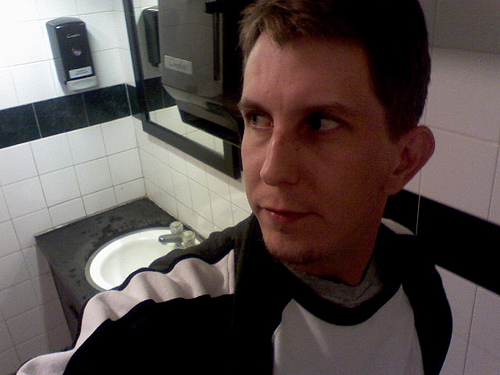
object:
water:
[100, 216, 116, 231]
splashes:
[110, 211, 121, 220]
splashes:
[102, 223, 117, 235]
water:
[94, 212, 114, 230]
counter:
[35, 192, 203, 302]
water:
[89, 220, 108, 234]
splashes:
[93, 214, 103, 221]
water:
[59, 218, 87, 234]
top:
[27, 222, 457, 375]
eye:
[298, 110, 351, 133]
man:
[15, 8, 455, 375]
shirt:
[20, 194, 454, 375]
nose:
[259, 119, 300, 187]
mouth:
[257, 202, 319, 226]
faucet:
[157, 223, 195, 247]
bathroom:
[0, 0, 499, 373]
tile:
[74, 157, 114, 196]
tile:
[421, 43, 497, 143]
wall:
[128, 7, 498, 372]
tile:
[100, 116, 136, 155]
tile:
[65, 125, 109, 164]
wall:
[2, 2, 145, 373]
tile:
[41, 172, 79, 206]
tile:
[0, 217, 19, 258]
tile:
[106, 152, 144, 186]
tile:
[49, 197, 84, 231]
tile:
[0, 175, 49, 218]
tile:
[2, 146, 36, 174]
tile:
[115, 177, 146, 207]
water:
[141, 234, 170, 259]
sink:
[85, 226, 205, 293]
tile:
[83, 189, 117, 214]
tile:
[27, 94, 87, 141]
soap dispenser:
[45, 15, 101, 95]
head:
[236, 0, 438, 266]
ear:
[382, 124, 436, 197]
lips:
[259, 203, 313, 224]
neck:
[283, 198, 383, 286]